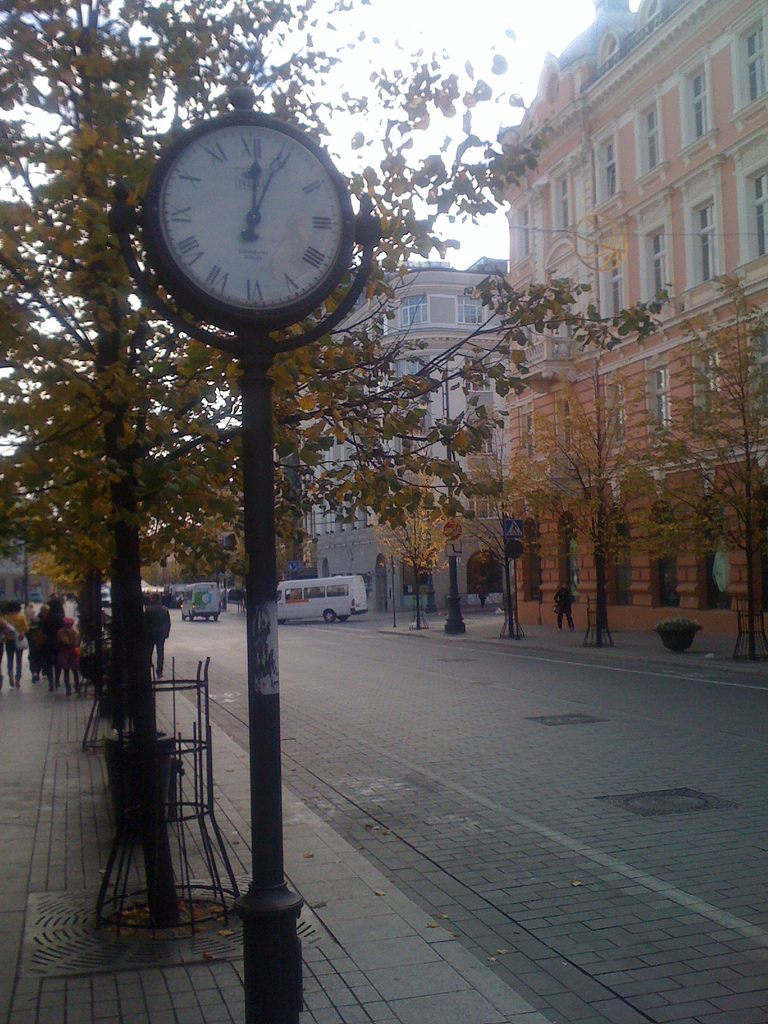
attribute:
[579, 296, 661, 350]
leaves — green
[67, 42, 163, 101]
leaves — green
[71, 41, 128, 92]
leaves — green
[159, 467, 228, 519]
leaves — green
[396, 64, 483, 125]
leaves — green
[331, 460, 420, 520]
leaves — green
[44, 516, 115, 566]
leaves — green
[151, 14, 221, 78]
leaves — green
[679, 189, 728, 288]
window — glass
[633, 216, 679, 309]
window — glass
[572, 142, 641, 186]
window — glass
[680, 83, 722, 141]
window — glass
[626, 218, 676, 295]
window — glass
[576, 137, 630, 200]
window — glass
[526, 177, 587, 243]
window — glass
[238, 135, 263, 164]
numeral — black , roman 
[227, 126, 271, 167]
numeral — black , roman 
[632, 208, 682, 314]
window — glass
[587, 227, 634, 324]
window — glass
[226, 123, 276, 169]
numeral — black , roman 